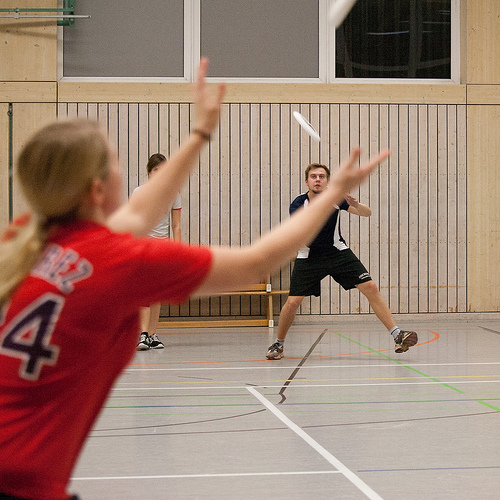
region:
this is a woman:
[16, 111, 163, 481]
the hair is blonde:
[28, 139, 67, 189]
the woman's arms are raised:
[118, 72, 372, 285]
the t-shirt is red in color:
[74, 321, 104, 368]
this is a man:
[269, 162, 419, 364]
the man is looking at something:
[308, 172, 323, 186]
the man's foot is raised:
[385, 322, 431, 354]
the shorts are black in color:
[318, 262, 362, 275]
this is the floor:
[324, 327, 361, 492]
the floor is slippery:
[223, 433, 388, 472]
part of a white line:
[291, 430, 328, 465]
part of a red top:
[59, 384, 95, 436]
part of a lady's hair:
[33, 165, 81, 221]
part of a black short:
[315, 264, 352, 285]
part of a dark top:
[308, 230, 328, 254]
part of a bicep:
[207, 247, 243, 282]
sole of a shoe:
[402, 334, 413, 346]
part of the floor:
[381, 431, 431, 466]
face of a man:
[306, 172, 321, 186]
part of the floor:
[356, 378, 415, 423]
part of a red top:
[37, 405, 92, 440]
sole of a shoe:
[398, 330, 413, 357]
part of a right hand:
[310, 147, 351, 210]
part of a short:
[307, 264, 340, 289]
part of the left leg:
[368, 299, 388, 317]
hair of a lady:
[28, 145, 84, 223]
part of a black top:
[313, 229, 331, 256]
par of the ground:
[384, 390, 447, 444]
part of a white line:
[304, 435, 349, 472]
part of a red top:
[84, 335, 131, 407]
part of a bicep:
[204, 255, 264, 307]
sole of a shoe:
[403, 339, 414, 351]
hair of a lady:
[21, 214, 54, 261]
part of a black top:
[320, 232, 335, 252]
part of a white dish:
[286, 106, 316, 152]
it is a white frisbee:
[293, 110, 320, 149]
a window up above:
[333, 1, 462, 76]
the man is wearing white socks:
[383, 325, 398, 336]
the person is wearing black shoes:
[140, 332, 165, 355]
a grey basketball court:
[203, 371, 277, 429]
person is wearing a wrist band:
[195, 125, 210, 146]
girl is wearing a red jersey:
[7, 220, 94, 474]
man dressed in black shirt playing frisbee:
[286, 172, 411, 338]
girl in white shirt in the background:
[136, 155, 186, 344]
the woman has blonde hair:
[15, 125, 121, 217]